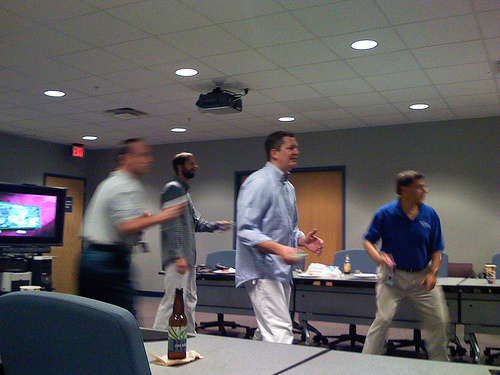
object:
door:
[232, 166, 346, 271]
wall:
[78, 108, 500, 285]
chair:
[0, 291, 151, 375]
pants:
[361, 264, 450, 362]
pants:
[244, 278, 294, 344]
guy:
[361, 169, 451, 361]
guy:
[234, 129, 324, 344]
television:
[0, 181, 67, 254]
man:
[151, 151, 234, 333]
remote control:
[383, 269, 396, 288]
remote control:
[290, 253, 310, 259]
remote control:
[218, 220, 235, 231]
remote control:
[161, 193, 193, 209]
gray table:
[157, 268, 499, 335]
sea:
[382, 219, 428, 254]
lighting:
[409, 102, 430, 110]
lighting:
[277, 115, 297, 122]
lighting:
[44, 89, 67, 98]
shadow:
[347, 25, 432, 120]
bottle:
[167, 287, 188, 359]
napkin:
[150, 349, 206, 367]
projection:
[195, 86, 251, 114]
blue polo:
[361, 196, 445, 271]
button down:
[233, 161, 305, 289]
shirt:
[361, 198, 446, 275]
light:
[349, 38, 376, 51]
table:
[139, 326, 500, 374]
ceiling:
[0, 0, 500, 151]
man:
[72, 137, 189, 325]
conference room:
[0, 0, 500, 375]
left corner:
[1, 274, 155, 374]